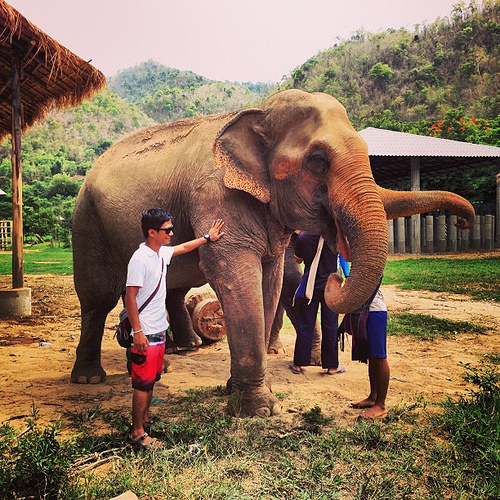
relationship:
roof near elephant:
[0, 3, 110, 143] [81, 97, 371, 337]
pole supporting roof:
[9, 69, 22, 288] [2, 3, 107, 163]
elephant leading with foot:
[69, 89, 388, 418] [203, 229, 284, 419]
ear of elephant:
[210, 105, 273, 205] [66, 85, 390, 418]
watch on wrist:
[201, 230, 212, 245] [199, 233, 210, 243]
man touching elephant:
[123, 207, 225, 452] [73, 95, 383, 408]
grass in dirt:
[0, 232, 499, 498] [0, 274, 500, 500]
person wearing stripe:
[288, 230, 343, 375] [303, 232, 326, 299]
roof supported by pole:
[0, 3, 110, 143] [1, 69, 28, 287]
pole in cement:
[1, 69, 28, 287] [2, 286, 32, 320]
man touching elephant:
[116, 206, 224, 449] [72, 90, 474, 414]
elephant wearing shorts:
[73, 95, 383, 408] [339, 300, 398, 361]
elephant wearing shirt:
[73, 95, 383, 408] [335, 254, 386, 313]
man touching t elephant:
[116, 206, 224, 449] [73, 95, 383, 408]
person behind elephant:
[329, 232, 391, 419] [66, 85, 390, 418]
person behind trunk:
[329, 232, 391, 419] [322, 171, 392, 315]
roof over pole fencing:
[352, 120, 497, 158] [382, 209, 492, 247]